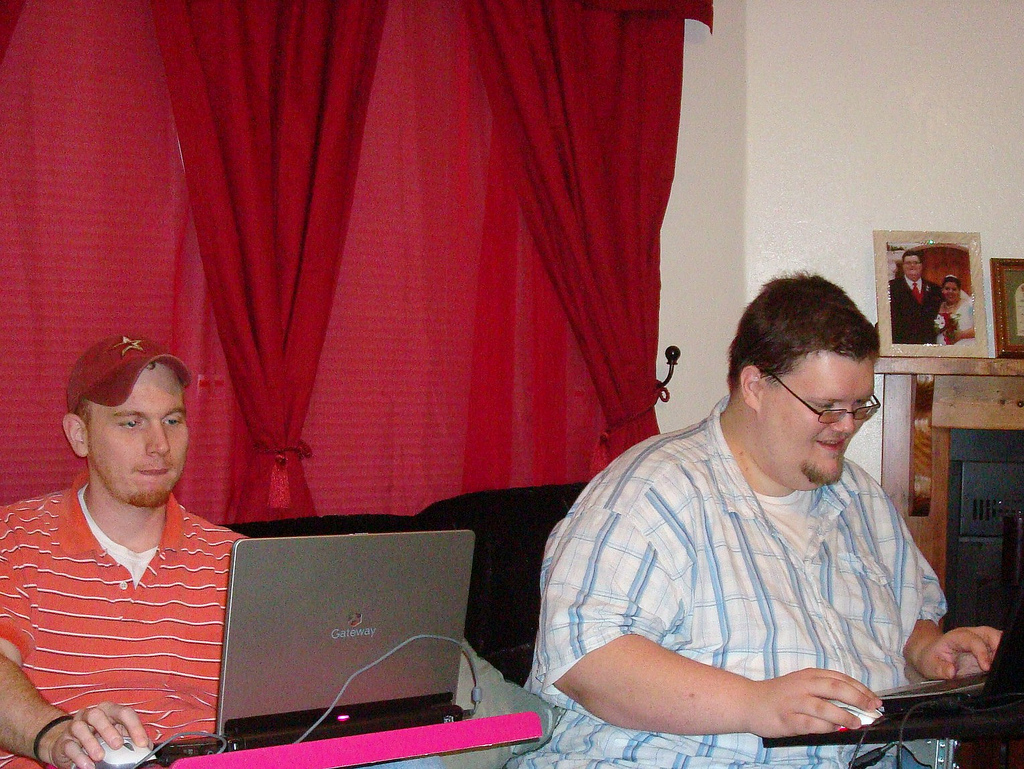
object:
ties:
[236, 447, 305, 509]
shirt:
[0, 473, 249, 769]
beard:
[800, 453, 846, 487]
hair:
[726, 270, 880, 395]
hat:
[65, 334, 193, 414]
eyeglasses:
[761, 371, 882, 424]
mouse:
[60, 735, 158, 767]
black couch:
[214, 482, 591, 689]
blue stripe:
[674, 463, 731, 674]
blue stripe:
[706, 458, 778, 680]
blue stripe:
[567, 513, 625, 659]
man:
[0, 336, 247, 769]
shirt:
[553, 474, 948, 761]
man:
[507, 270, 1000, 769]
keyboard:
[870, 673, 991, 719]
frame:
[873, 230, 988, 358]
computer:
[153, 529, 476, 756]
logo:
[112, 335, 144, 357]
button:
[800, 564, 805, 573]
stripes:
[521, 398, 957, 769]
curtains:
[156, 5, 711, 526]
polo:
[0, 471, 249, 769]